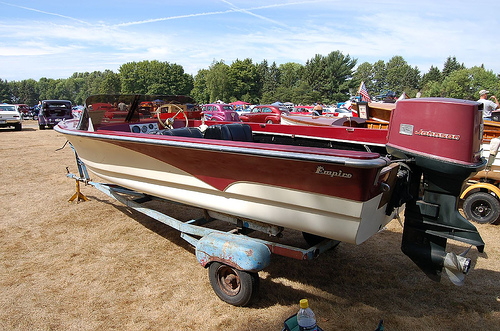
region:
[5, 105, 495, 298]
the boat is used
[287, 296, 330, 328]
the bottle is a water bottle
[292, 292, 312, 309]
the top is yellow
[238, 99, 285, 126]
the cars are red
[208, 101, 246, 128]
the car is purple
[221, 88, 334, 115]
the cars are parked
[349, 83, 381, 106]
the flag is american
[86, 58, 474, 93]
the trees are in the background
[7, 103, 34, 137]
the car is white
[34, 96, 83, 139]
the car is black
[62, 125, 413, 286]
the boat is red and white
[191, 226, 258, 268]
the mudgear is blue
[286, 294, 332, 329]
the bottle has water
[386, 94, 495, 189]
the engine is red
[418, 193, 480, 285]
the proppeller is behind the boat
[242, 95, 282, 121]
the car is red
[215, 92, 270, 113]
the cars are parked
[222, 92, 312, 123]
the cars are classic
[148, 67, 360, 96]
trees are in the background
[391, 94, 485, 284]
Boat outboard motor.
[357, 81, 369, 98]
American flag in the wind.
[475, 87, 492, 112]
Man wearing a beige cap.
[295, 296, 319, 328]
Beverage bottle with yellow cap.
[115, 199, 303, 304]
Rusty boat trailer.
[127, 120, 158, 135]
Dash instrument Panel on a boat.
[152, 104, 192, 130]
Boat's steering wheel.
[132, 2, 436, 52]
Blue and white sky.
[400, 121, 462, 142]
Brand name on outboard motor.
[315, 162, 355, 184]
Brand name on side of boat.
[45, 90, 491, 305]
Long white and red boat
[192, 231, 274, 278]
Rusted blue left wheel cover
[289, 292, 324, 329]
Bottle with yellow top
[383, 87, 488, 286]
Red boat motor engine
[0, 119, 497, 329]
Dry parched grass with cars and boats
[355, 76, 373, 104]
American flag waved across lot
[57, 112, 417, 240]
Red and white surface on Empico boat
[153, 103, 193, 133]
Steering wheel on boat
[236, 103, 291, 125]
Red car parked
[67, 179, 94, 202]
Yellow jack holding boat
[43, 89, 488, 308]
a red and white boat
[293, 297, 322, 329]
water bottle with a yellow cap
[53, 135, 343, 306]
old blue and red boat trailer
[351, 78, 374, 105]
an American flag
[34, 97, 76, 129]
a black vintage car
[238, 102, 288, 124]
a red vintage car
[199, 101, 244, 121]
a pink vintage car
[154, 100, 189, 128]
the steering wheel of the boat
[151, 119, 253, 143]
black seats on the boat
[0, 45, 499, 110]
a row of trees in the background